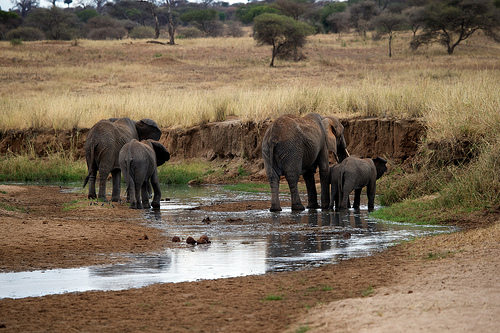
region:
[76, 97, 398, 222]
rear view of four elephants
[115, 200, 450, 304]
shallow body of water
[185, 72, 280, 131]
dried brown grass on ledge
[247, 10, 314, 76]
tree with green leaves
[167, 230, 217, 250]
rocks on water's edge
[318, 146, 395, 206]
young elephant walking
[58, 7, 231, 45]
green trees on horizon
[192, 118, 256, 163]
dirt ledge overlooking water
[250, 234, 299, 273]
elephant reflection in water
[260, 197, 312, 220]
elephant feet in water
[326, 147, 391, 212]
a baby elephant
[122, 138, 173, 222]
a baby elephant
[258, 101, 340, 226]
a huge elephant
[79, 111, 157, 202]
a huge elephant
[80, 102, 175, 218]
two elephants beside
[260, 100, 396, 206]
two elephants beside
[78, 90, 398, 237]
four elephants in water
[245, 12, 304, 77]
a green tree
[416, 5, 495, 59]
a green tree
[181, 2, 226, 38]
a green tree in the forest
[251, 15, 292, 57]
green trees in the background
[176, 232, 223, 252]
elephant feces in the water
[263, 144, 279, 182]
the elephants tail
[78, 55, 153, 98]
some dried out yellow grass in the background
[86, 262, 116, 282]
a stream of water for the elephants to drink.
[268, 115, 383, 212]
two elephants together in the water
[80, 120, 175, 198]
there are two little elephants in the water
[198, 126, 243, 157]
it is a bank up ahead in front of the elephants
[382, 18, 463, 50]
lots of trees in the background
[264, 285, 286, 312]
a tiny spot of green grass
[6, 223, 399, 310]
watering hole for thirsty animals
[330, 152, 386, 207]
baby elephant walking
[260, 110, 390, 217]
mother elephant and baby elephant walking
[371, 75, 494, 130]
dry vegetation in a savannah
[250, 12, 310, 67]
tree in a savannah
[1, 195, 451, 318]
watering hole with little water in it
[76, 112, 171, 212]
mother elephant and her older baby elephant walking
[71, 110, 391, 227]
group of elephants at a watering hole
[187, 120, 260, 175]
eroding soil at the edge of a watering hole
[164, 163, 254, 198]
green vegetation growing at the water's edge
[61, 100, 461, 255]
Four elephants in water.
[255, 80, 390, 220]
One big elephant and one little elephant.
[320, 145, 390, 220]
A small grey elephant.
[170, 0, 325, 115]
Brown grassy land with small tree.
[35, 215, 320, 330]
Slow running river.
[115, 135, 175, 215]
Elephant with big ears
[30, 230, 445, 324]
Dark brown river bank.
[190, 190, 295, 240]
Small dirt island in middle of river.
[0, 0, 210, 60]
Lots of small green bushes.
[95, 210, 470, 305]
Rocks in water.